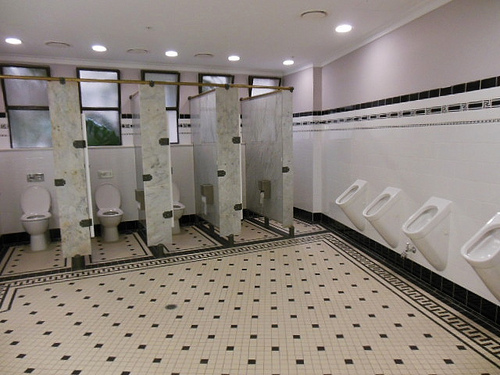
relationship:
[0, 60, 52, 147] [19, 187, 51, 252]
window above kemode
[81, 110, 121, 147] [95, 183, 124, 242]
window above kemode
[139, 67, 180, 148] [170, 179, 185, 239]
window above kemode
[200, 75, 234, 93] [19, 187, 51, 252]
window above kemode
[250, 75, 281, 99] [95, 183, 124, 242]
window above kemode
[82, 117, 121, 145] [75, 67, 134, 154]
bush in window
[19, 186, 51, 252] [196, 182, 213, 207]
kemode paper dispensers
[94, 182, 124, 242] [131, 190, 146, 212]
kemode paper dispensers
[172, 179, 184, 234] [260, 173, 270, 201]
kemode paper dispensers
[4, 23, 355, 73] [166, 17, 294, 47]
lights in ceiling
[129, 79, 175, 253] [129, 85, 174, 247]
marble in stall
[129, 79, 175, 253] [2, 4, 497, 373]
marble in bathroom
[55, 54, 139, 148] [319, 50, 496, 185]
window in wall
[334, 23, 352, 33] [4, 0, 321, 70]
lights in ceiling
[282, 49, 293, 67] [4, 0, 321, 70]
lights in ceiling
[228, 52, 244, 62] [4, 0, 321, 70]
lights in ceiling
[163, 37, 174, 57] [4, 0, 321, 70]
lights in ceiling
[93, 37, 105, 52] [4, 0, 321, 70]
lights in ceiling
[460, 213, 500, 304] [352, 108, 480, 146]
urinal on wall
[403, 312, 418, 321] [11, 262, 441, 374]
tile on floor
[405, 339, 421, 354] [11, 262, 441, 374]
tile on floor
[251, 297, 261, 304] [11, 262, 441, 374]
tile on floor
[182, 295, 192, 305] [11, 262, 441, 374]
tile on floor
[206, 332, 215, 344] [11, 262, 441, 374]
tile on floor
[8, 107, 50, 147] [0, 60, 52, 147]
glass on window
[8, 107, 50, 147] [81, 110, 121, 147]
glass on window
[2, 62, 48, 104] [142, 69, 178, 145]
glass on window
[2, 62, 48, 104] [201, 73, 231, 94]
glass on window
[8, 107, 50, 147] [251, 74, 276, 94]
glass on window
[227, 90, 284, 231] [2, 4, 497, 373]
stalls in bathroom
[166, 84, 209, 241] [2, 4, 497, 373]
stalls in bathroom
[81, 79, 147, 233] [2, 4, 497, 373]
stalls in bathroom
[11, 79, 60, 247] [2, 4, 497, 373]
stalls in bathroom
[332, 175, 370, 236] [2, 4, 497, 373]
urinal in bathroom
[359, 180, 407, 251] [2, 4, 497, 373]
urinal in bathroom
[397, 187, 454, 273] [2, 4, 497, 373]
urinal in bathroom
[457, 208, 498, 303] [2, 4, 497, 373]
urinal in bathroom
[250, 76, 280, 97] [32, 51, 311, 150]
window in bathroom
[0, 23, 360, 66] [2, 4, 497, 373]
lights in bathroom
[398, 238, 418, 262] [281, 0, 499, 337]
water line on wall